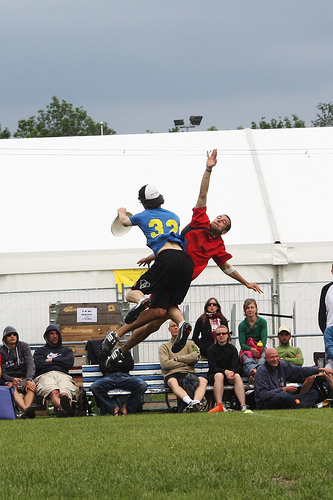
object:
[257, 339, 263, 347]
top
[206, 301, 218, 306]
sunglasses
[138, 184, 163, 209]
hat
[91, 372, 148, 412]
jeans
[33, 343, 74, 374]
shirt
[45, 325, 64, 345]
hood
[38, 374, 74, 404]
shorts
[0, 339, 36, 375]
sweatshirt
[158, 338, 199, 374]
sweater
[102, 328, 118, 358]
shoe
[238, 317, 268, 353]
shirt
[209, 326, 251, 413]
spectator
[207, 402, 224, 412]
cone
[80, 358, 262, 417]
bench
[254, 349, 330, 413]
man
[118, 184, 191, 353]
man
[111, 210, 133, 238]
frisbee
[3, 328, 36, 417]
man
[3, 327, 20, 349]
hood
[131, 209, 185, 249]
shirt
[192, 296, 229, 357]
woman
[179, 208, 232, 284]
jersey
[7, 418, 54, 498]
grass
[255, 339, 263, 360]
water bottle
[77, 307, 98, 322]
sign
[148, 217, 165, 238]
number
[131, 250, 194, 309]
shorts